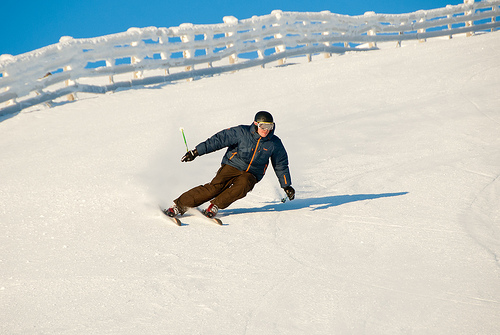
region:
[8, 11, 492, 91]
a long white fence.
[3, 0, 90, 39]
a blue sky.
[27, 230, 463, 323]
the snow is snow white.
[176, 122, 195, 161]
a green ski stick.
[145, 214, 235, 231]
a man is standing on brown skis.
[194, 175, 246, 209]
a man is wearing brown pants.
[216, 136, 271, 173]
a man is wearing a blue and orange coat.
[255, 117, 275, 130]
a man is wearing black gloves.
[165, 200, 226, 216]
a man is wearing burgundy sneakers.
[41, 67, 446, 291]
a man is skiing in the snow.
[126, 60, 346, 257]
The man is skiing down a hill.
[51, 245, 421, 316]
Snow is on the ground.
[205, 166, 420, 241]
The shadow of the man.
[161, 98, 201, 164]
The man is holding a ski pole.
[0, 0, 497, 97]
The fence is covered in snow.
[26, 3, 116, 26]
The ski is blue.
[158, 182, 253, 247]
The man has two skis attached to his feet.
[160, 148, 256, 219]
The man is wearing brown ski pants.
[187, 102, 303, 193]
The man is wearing a blue jacket.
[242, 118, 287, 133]
The man is wearing goggles.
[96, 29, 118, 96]
snow covered fence post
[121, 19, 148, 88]
snow covered fence post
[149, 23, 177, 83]
snow covered fence post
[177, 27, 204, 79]
snow covered fence post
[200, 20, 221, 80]
snow covered fence post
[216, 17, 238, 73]
snow covered fence post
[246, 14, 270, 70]
snow covered fence post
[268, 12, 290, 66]
snow covered fence post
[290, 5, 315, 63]
snow covered fence post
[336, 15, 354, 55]
snow covered fence post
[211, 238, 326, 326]
the snow is white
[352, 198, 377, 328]
the snow is white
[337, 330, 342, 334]
the snow is white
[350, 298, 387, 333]
the snow is white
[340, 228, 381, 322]
the snow is white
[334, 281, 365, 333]
the snow is white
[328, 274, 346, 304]
the snow is white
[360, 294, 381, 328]
the snow is white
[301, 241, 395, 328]
the snow is white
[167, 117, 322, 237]
man skiing down hill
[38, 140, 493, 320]
snow all over the ground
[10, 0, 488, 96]
wooden fence in background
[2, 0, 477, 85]
fence covered in snow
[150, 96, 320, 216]
man wearing blue and orange jacket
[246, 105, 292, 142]
man wearing yellow goggles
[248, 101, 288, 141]
man wearing black helmet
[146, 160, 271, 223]
man wearing brown pants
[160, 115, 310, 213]
man using green poles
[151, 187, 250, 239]
man wearing red boots